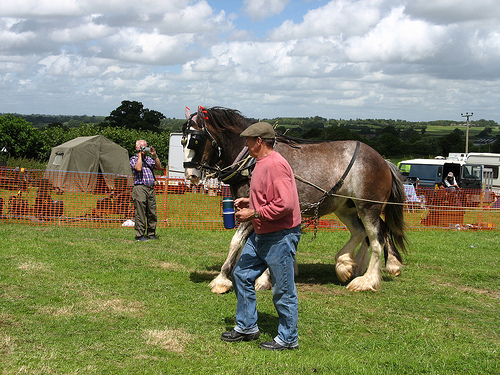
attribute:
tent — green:
[40, 134, 135, 197]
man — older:
[219, 120, 304, 353]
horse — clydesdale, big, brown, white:
[179, 102, 410, 294]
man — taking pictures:
[128, 136, 166, 242]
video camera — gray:
[139, 144, 155, 158]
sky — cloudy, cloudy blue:
[1, 0, 499, 123]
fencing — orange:
[0, 165, 499, 234]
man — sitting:
[443, 171, 461, 194]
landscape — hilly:
[1, 111, 499, 159]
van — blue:
[396, 156, 485, 202]